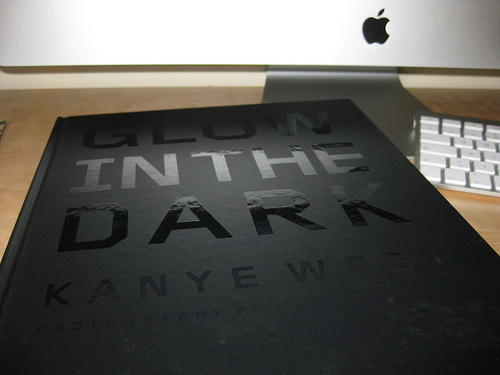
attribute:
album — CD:
[0, 83, 485, 373]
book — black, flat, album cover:
[10, 95, 496, 372]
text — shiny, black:
[67, 133, 371, 200]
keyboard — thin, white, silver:
[412, 105, 500, 193]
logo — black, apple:
[360, 5, 392, 49]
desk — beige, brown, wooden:
[14, 98, 43, 117]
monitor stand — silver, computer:
[2, 1, 495, 118]